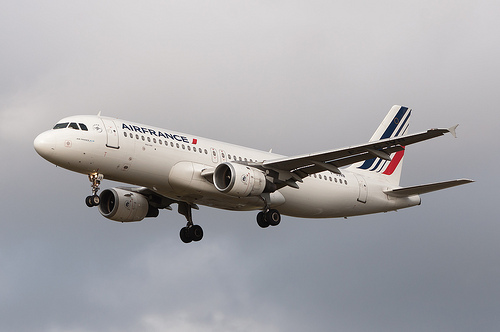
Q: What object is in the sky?
A: Plane.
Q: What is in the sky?
A: Jet plane.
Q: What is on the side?
A: Left wing.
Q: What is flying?
A: Plane.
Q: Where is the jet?
A: Flying.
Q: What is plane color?
A: White.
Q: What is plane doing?
A: Taking off.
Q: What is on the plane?
A: Windows.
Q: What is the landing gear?
A: Down.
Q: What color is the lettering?
A: Blue.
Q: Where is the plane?
A: In the air.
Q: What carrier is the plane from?
A: Air France.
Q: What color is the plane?
A: White.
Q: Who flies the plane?
A: Pilot.